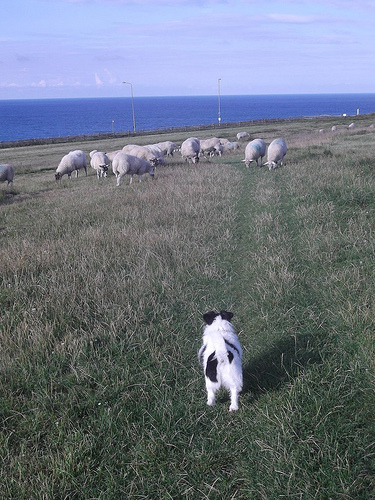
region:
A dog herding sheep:
[47, 127, 297, 419]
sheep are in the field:
[59, 122, 330, 202]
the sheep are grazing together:
[83, 132, 293, 198]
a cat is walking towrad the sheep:
[172, 283, 272, 422]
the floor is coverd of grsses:
[49, 383, 171, 496]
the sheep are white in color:
[65, 130, 178, 203]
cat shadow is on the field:
[249, 316, 317, 404]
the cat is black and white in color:
[203, 296, 239, 397]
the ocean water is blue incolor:
[57, 84, 102, 127]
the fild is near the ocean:
[95, 104, 155, 138]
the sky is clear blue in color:
[84, 27, 154, 80]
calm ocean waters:
[34, 98, 235, 125]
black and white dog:
[188, 306, 255, 405]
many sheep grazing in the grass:
[46, 143, 289, 175]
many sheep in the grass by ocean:
[29, 117, 289, 191]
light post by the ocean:
[122, 73, 149, 140]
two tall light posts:
[115, 69, 228, 132]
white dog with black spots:
[201, 302, 255, 406]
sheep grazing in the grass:
[45, 143, 86, 179]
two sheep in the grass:
[245, 135, 290, 166]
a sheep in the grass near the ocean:
[50, 146, 85, 177]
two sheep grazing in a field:
[241, 136, 309, 177]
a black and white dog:
[119, 271, 338, 462]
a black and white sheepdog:
[81, 294, 325, 448]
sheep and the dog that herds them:
[12, 59, 336, 416]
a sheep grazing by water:
[40, 82, 88, 192]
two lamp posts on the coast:
[87, 56, 230, 134]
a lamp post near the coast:
[109, 66, 154, 139]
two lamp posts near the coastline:
[97, 62, 231, 136]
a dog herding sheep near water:
[24, 79, 315, 411]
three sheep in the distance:
[310, 119, 366, 164]